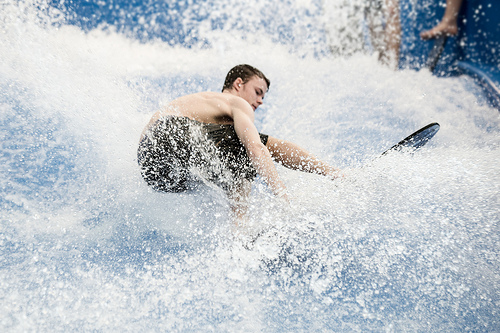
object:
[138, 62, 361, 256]
boy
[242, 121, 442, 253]
surfboard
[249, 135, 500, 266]
waves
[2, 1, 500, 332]
water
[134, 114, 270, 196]
shorts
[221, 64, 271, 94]
hair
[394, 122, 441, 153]
tip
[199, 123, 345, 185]
leg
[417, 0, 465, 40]
leg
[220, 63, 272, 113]
head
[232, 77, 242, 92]
ear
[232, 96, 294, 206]
arm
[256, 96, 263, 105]
nose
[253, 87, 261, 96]
eye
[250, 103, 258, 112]
mouth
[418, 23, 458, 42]
foot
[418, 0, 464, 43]
person